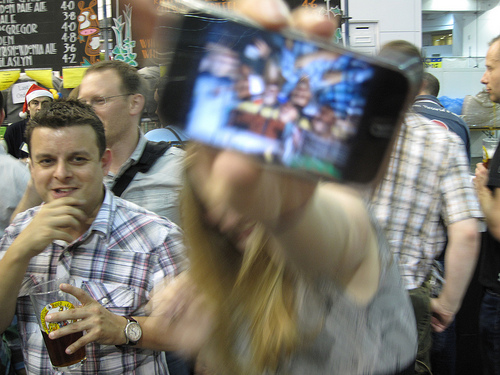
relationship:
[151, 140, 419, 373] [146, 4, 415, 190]
girl holds up phone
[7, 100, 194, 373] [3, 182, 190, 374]
guy in plaid shirt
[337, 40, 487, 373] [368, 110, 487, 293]
guy in plaid shirt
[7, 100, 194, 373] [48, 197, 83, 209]
guy touching chin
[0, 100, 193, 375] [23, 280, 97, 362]
guy holding glass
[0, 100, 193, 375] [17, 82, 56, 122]
guy wearing hat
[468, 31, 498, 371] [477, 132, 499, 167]
guy holding glass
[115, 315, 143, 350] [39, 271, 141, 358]
watch on hand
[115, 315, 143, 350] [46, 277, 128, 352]
watch on hand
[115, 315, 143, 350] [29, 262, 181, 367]
watch on hand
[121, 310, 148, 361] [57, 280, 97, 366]
watch on hand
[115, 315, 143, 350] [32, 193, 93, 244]
watch on hand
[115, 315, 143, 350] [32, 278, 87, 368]
watch on hand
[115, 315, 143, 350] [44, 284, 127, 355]
watch on hand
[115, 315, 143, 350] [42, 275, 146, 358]
watch on hand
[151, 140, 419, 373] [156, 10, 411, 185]
girl holding up cell phone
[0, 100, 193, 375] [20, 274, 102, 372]
guy holding glass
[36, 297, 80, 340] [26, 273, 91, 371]
decal on glass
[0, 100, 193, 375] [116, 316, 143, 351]
guy wearing watch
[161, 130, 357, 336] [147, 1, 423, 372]
hair on a person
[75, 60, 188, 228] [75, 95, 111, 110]
man wearing eyeglasses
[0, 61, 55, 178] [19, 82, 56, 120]
man wearing hat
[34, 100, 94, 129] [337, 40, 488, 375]
hair on guy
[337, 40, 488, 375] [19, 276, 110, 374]
guy holding glass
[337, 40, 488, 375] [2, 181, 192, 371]
guy wearing shirt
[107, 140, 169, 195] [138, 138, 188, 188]
strap on shoulder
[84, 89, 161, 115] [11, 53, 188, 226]
glasses on a person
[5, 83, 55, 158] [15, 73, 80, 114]
man wearing a hat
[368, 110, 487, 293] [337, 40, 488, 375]
plaid shirt on a guy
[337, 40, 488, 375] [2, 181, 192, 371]
guy wearing a shirt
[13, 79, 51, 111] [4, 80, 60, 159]
hat on man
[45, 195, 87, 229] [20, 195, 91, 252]
chin on hand